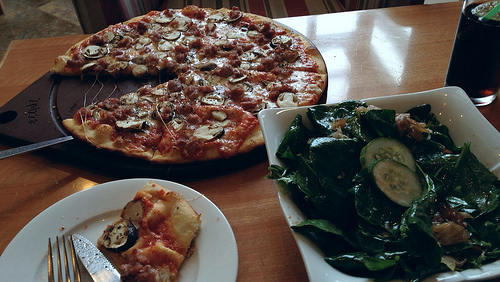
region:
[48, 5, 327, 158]
a pizza with mushrooms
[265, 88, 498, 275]
cooked spinach in a white square bowl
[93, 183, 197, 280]
a slice of pizza in a white plate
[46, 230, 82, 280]
top of a fork on a white plate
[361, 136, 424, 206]
slices of cucumber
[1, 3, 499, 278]
a wooden table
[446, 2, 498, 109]
a glass of soda on a table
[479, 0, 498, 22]
a green straw in a glass of soda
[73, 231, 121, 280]
edge of a knife on a white plate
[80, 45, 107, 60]
a slice of mushroom on a pizza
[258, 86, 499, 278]
a square white plate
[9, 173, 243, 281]
a round white plate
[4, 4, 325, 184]
a round pizza pan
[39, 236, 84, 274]
a fork on a white plate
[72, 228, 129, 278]
a knife on a white plate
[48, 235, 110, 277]
a knife and a fork on a white plate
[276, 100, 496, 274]
green salad in a plate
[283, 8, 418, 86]
a reflection on the table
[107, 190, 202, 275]
pizza on a plate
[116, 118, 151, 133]
mushrooms on a pizza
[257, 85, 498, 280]
The bowl has a salad on it.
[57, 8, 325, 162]
The pizza has eight slices.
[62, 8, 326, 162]
The pizza is under the table.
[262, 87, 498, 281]
The salad in under the table.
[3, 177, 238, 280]
There is a pizza on the dish.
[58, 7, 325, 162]
The pizza does not have one slice.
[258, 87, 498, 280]
The color of the salad is green.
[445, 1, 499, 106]
The glass is empty of soda.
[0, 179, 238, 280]
Over the dish there is a fork and knife.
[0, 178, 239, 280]
The dish is near to the salad.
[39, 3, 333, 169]
a pizza with one slice cut out of it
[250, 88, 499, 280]
a small side salad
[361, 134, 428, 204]
sliced cucumber in the salad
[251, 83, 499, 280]
a white square bowl with a salad in it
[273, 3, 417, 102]
a reflection of light from the window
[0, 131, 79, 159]
a spatula underneath the pizza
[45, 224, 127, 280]
a fork and knife on the plate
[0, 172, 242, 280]
a slice of pizza on a white plate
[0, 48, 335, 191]
a dark brown serving plate for the pizza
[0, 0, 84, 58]
granite styled tiles on the floor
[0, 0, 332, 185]
pizza pie with a missing piece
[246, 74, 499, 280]
spinach salad with cucumber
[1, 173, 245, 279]
piece of pizza on a plate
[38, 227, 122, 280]
fork and knife lying on top of pizza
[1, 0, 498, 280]
Wood grain table with food on top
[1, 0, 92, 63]
tile covering the floor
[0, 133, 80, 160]
utensil for serving pizza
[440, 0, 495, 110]
glass of soda-like beverage on table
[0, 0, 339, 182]
skillet-like pan for pizza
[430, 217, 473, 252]
Walnut on top of spinach